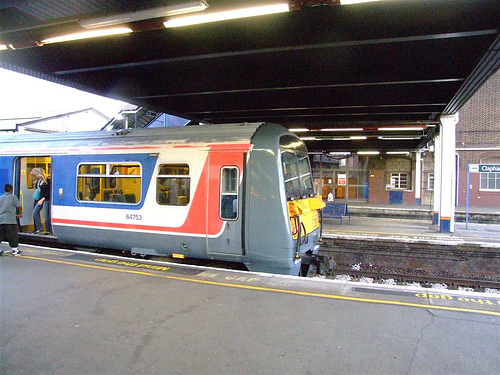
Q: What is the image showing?
A: It is showing a station.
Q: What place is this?
A: It is a station.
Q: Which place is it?
A: It is a station.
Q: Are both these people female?
A: No, they are both male and female.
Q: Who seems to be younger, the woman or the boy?
A: The boy is younger than the woman.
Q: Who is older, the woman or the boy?
A: The woman is older than the boy.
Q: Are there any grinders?
A: No, there are no grinders.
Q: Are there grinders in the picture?
A: No, there are no grinders.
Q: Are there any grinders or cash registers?
A: No, there are no grinders or cash registers.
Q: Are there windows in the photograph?
A: Yes, there is a window.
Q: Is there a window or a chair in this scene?
A: Yes, there is a window.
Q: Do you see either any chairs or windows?
A: Yes, there is a window.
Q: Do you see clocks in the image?
A: No, there are no clocks.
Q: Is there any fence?
A: No, there are no fences.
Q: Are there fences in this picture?
A: No, there are no fences.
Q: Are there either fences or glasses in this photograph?
A: No, there are no fences or glasses.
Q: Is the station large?
A: Yes, the station is large.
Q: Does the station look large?
A: Yes, the station is large.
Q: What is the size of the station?
A: The station is large.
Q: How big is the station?
A: The station is large.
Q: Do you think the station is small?
A: No, the station is large.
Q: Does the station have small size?
A: No, the station is large.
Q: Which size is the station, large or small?
A: The station is large.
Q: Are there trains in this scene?
A: Yes, there is a train.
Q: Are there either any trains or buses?
A: Yes, there is a train.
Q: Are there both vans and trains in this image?
A: No, there is a train but no vans.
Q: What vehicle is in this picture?
A: The vehicle is a train.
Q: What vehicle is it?
A: The vehicle is a train.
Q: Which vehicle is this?
A: This is a train.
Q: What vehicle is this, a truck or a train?
A: This is a train.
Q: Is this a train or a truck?
A: This is a train.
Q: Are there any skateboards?
A: No, there are no skateboards.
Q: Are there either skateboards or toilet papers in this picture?
A: No, there are no skateboards or toilet papers.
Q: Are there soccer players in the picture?
A: No, there are no soccer players.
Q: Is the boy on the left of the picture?
A: Yes, the boy is on the left of the image.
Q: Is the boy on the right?
A: No, the boy is on the left of the image.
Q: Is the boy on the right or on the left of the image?
A: The boy is on the left of the image.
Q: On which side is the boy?
A: The boy is on the left of the image.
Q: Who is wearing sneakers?
A: The boy is wearing sneakers.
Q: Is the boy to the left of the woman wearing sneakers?
A: Yes, the boy is wearing sneakers.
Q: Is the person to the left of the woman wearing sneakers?
A: Yes, the boy is wearing sneakers.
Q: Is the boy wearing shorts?
A: No, the boy is wearing sneakers.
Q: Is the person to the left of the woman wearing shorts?
A: No, the boy is wearing sneakers.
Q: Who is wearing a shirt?
A: The boy is wearing a shirt.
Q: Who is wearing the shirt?
A: The boy is wearing a shirt.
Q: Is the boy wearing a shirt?
A: Yes, the boy is wearing a shirt.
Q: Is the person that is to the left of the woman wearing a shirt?
A: Yes, the boy is wearing a shirt.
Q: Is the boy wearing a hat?
A: No, the boy is wearing a shirt.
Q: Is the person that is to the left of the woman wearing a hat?
A: No, the boy is wearing a shirt.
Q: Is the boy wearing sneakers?
A: Yes, the boy is wearing sneakers.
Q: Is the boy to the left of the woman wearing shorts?
A: No, the boy is wearing sneakers.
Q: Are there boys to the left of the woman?
A: Yes, there is a boy to the left of the woman.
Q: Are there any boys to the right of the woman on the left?
A: No, the boy is to the left of the woman.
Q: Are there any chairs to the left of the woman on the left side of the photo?
A: No, there is a boy to the left of the woman.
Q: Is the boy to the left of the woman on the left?
A: Yes, the boy is to the left of the woman.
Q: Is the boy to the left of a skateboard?
A: No, the boy is to the left of the woman.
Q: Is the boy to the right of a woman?
A: No, the boy is to the left of a woman.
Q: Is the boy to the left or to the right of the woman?
A: The boy is to the left of the woman.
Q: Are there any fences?
A: No, there are no fences.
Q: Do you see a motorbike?
A: No, there are no motorcycles.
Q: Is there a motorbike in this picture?
A: No, there are no motorcycles.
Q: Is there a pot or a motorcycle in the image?
A: No, there are no motorcycles or pots.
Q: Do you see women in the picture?
A: Yes, there is a woman.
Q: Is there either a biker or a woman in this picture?
A: Yes, there is a woman.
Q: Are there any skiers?
A: No, there are no skiers.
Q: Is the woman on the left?
A: Yes, the woman is on the left of the image.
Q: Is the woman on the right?
A: No, the woman is on the left of the image.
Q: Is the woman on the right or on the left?
A: The woman is on the left of the image.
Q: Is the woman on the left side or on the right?
A: The woman is on the left of the image.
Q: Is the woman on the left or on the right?
A: The woman is on the left of the image.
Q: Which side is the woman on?
A: The woman is on the left of the image.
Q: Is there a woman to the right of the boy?
A: Yes, there is a woman to the right of the boy.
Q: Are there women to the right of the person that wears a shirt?
A: Yes, there is a woman to the right of the boy.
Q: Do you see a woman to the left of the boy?
A: No, the woman is to the right of the boy.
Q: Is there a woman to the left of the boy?
A: No, the woman is to the right of the boy.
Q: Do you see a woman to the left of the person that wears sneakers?
A: No, the woman is to the right of the boy.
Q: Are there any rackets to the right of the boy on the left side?
A: No, there is a woman to the right of the boy.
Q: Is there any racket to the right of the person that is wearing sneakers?
A: No, there is a woman to the right of the boy.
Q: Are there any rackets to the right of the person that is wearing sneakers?
A: No, there is a woman to the right of the boy.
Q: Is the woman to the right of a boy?
A: Yes, the woman is to the right of a boy.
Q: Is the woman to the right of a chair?
A: No, the woman is to the right of a boy.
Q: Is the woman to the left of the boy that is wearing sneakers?
A: No, the woman is to the right of the boy.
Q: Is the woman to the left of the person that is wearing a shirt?
A: No, the woman is to the right of the boy.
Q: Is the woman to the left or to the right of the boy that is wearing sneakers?
A: The woman is to the right of the boy.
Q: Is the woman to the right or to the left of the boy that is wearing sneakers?
A: The woman is to the right of the boy.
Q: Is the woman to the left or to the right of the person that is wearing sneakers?
A: The woman is to the right of the boy.